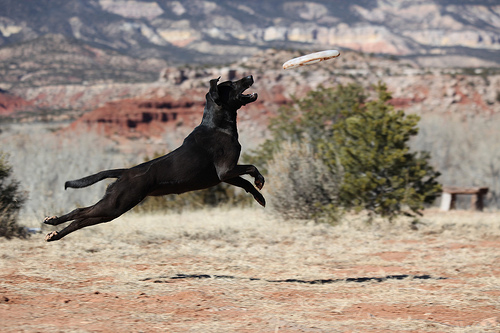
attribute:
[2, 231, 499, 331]
dirt — red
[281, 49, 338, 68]
frisbee — white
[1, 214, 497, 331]
grass — dead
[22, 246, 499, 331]
sand — brown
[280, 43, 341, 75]
frisbee — white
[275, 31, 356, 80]
frisbee — white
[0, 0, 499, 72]
hillside — gray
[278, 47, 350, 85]
frisbee — white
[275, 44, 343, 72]
frisbee — white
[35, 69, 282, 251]
dog — black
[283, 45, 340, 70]
frisbee — white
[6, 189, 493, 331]
area — arid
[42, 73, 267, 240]
dog — black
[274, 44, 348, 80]
fisbee — white, brown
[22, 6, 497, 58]
mountain — big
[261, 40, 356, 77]
frisbee — white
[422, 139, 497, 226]
bench — stone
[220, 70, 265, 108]
mouth — open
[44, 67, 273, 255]
dog — jumps